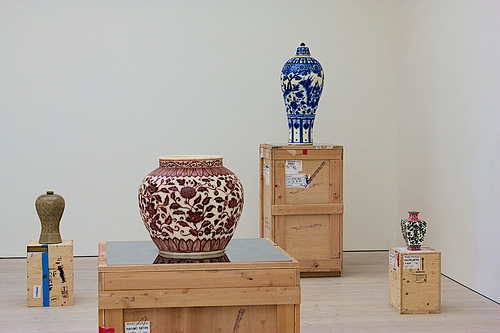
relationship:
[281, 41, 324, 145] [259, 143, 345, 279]
vase on top of crate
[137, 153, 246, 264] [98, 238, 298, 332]
vase on top of crate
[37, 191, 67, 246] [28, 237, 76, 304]
vase on top of crate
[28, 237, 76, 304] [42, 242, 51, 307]
crate has stripe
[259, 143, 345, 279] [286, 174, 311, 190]
crate has sticker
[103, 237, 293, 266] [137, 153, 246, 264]
surface under vase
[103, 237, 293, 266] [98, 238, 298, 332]
surface on top of crate